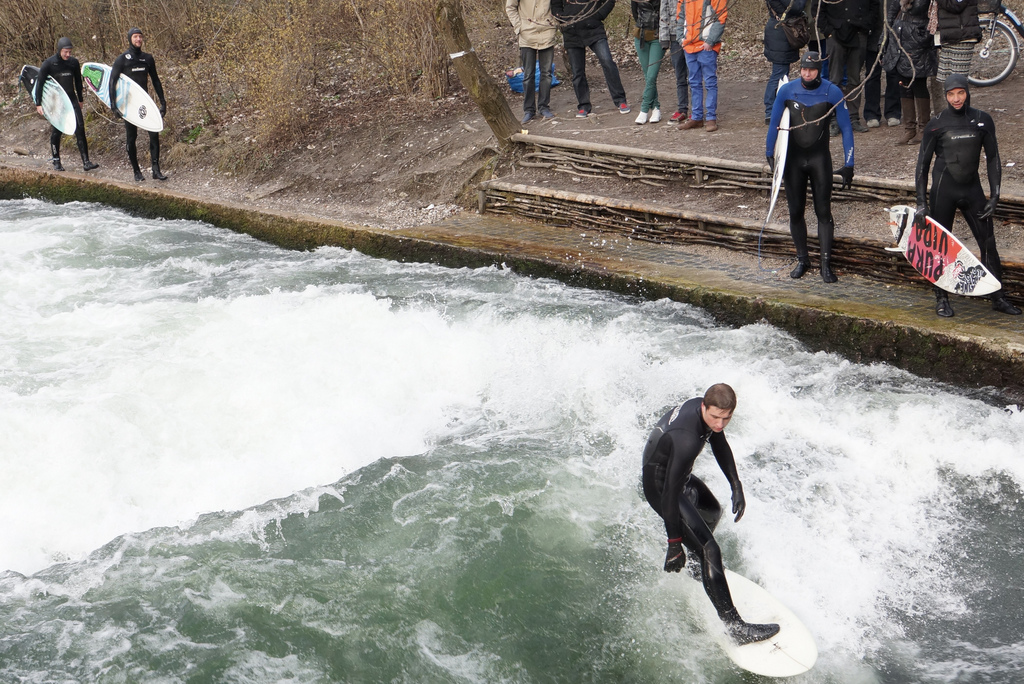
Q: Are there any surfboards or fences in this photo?
A: Yes, there is a surfboard.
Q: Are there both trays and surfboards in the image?
A: No, there is a surfboard but no trays.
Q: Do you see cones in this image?
A: No, there are no cones.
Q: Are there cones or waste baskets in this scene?
A: No, there are no cones or waste baskets.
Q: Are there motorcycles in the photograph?
A: No, there are no motorcycles.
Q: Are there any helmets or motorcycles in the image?
A: No, there are no motorcycles or helmets.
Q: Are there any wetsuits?
A: Yes, there is a wetsuit.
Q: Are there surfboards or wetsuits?
A: Yes, there is a wetsuit.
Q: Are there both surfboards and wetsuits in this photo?
A: Yes, there are both a wetsuit and a surfboard.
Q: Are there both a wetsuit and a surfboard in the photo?
A: Yes, there are both a wetsuit and a surfboard.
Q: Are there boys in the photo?
A: No, there are no boys.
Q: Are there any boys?
A: No, there are no boys.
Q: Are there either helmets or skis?
A: No, there are no helmets or skis.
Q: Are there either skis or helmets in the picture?
A: No, there are no helmets or skis.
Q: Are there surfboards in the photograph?
A: Yes, there is a surfboard.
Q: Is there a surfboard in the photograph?
A: Yes, there is a surfboard.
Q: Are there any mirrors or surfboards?
A: Yes, there is a surfboard.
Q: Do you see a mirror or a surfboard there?
A: Yes, there is a surfboard.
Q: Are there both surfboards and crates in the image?
A: No, there is a surfboard but no crates.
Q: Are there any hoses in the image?
A: No, there are no hoses.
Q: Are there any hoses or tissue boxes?
A: No, there are no hoses or tissue boxes.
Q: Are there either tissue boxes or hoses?
A: No, there are no hoses or tissue boxes.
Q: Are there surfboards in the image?
A: Yes, there is a surfboard.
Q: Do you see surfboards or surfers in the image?
A: Yes, there is a surfboard.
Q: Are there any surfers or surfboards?
A: Yes, there is a surfboard.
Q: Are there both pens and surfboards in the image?
A: No, there is a surfboard but no pens.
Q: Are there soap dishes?
A: No, there are no soap dishes.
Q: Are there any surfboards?
A: Yes, there is a surfboard.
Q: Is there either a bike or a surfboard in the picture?
A: Yes, there is a surfboard.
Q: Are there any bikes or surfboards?
A: Yes, there is a surfboard.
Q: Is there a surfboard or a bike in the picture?
A: Yes, there is a surfboard.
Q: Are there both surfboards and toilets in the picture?
A: No, there is a surfboard but no toilets.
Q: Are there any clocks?
A: No, there are no clocks.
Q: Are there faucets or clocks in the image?
A: No, there are no clocks or faucets.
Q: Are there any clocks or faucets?
A: No, there are no clocks or faucets.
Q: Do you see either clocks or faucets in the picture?
A: No, there are no clocks or faucets.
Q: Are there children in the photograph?
A: No, there are no children.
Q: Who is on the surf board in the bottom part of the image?
A: The man is on the surfboard.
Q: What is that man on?
A: The man is on the surfboard.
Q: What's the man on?
A: The man is on the surfboard.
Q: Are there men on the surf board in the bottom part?
A: Yes, there is a man on the surfboard.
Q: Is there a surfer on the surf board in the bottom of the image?
A: No, there is a man on the surfboard.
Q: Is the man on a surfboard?
A: Yes, the man is on a surfboard.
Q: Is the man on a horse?
A: No, the man is on a surfboard.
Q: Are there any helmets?
A: No, there are no helmets.